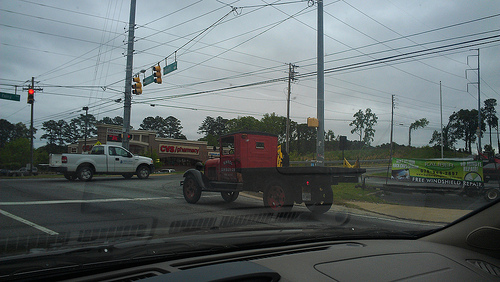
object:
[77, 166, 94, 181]
tire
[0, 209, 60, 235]
white lines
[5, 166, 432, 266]
road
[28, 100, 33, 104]
light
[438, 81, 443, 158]
poles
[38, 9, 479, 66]
lines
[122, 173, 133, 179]
wheel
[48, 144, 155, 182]
pickup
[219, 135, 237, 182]
door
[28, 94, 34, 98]
light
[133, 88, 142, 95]
light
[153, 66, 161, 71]
light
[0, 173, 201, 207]
intersection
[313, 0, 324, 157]
pole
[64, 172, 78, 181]
tire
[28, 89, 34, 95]
light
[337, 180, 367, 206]
grass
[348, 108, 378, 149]
tree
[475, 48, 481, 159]
pole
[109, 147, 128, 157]
window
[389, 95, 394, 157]
pole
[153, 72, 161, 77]
lights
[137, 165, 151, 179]
tire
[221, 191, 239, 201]
tire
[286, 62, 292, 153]
pole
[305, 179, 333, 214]
back wheel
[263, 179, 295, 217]
back wheel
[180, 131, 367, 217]
antique truck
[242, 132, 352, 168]
empty back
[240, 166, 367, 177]
bed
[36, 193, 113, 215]
tarmacked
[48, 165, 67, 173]
tailgate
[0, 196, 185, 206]
lines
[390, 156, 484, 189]
sign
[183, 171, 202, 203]
tire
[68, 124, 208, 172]
pharmacy